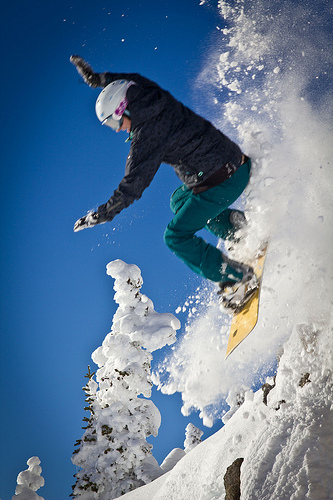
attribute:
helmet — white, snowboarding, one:
[90, 81, 147, 133]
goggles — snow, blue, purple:
[104, 103, 129, 130]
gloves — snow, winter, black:
[68, 53, 93, 232]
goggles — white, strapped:
[102, 89, 133, 130]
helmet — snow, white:
[91, 75, 135, 134]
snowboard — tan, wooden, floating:
[207, 224, 295, 370]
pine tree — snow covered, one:
[67, 364, 105, 499]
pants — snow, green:
[157, 155, 269, 285]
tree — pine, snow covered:
[70, 259, 181, 498]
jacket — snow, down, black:
[127, 73, 257, 200]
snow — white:
[243, 383, 331, 499]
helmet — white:
[94, 72, 143, 120]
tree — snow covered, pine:
[91, 333, 157, 377]